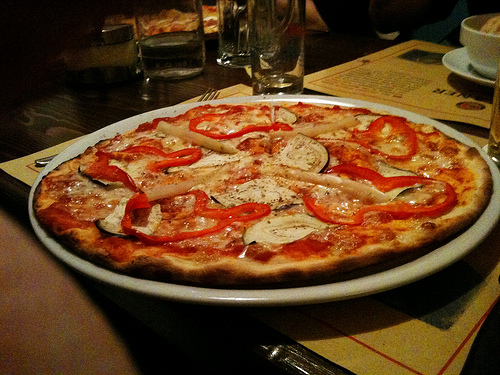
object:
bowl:
[453, 21, 497, 88]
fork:
[191, 86, 226, 103]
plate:
[25, 89, 499, 313]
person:
[276, 2, 427, 47]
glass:
[245, 0, 313, 97]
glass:
[130, 0, 208, 85]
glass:
[213, 1, 258, 76]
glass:
[66, 13, 146, 82]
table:
[151, 3, 499, 98]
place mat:
[0, 79, 498, 372]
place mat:
[304, 36, 498, 131]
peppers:
[94, 110, 456, 242]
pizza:
[50, 94, 493, 293]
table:
[0, 28, 480, 373]